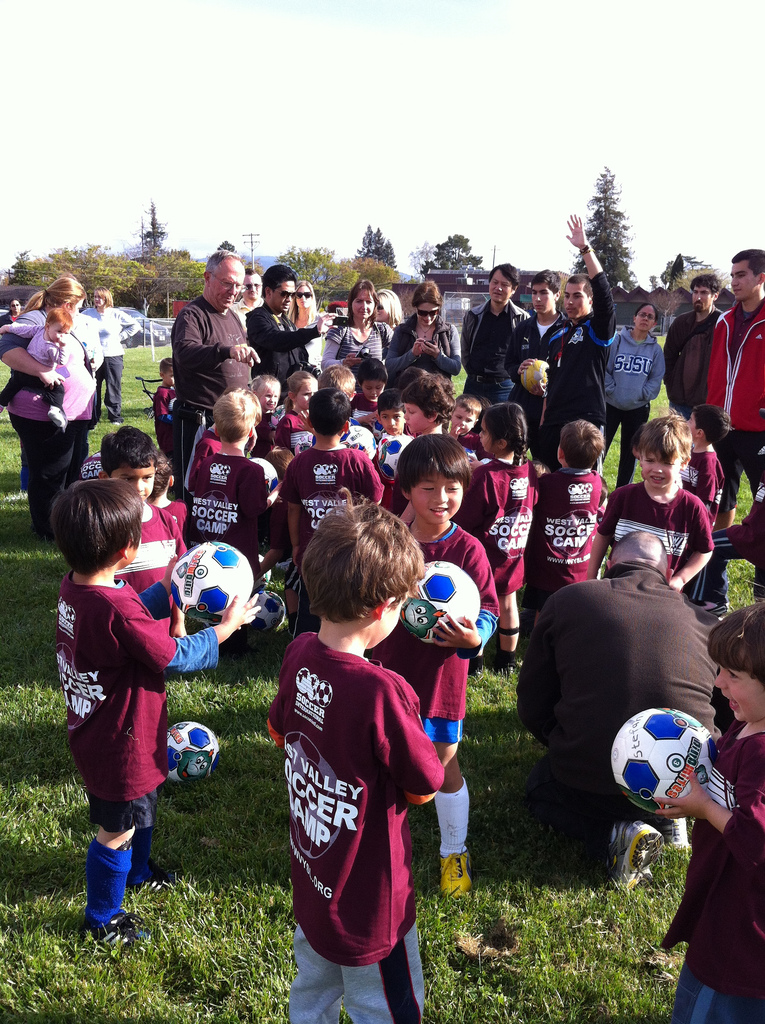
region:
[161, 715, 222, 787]
Soccer ball on the ground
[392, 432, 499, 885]
The boy holding the ball facing the camera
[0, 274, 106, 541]
Mother holding a baby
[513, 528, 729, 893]
Man kneeling in the brown shirt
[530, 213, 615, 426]
Man raising his hand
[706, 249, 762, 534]
Person in the red zip up jacket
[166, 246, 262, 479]
Older man in the brown long sleeve shirt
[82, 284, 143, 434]
Woman in the white shirt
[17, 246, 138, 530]
lady holding a toddler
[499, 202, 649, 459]
guy with hand raised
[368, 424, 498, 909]
boy wearing yellow soccer shoe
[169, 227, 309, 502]
man pointing his finger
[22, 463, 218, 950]
boy has blue socks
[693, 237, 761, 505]
guy wearing red jacket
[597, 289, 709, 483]
lady wearing gray sweatshirt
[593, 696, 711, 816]
white and blue soccer ball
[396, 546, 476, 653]
white and blue soccer ball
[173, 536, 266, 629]
white and blue soccer ball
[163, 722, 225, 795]
white and blue soccer ball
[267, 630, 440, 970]
burgundy and white shirt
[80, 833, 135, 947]
blue sock on leg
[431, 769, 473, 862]
white sock on leg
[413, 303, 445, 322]
sunglasses on woman's face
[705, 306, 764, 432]
red jacket on man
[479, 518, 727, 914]
a man in brown shirt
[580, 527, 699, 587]
the back of a man's head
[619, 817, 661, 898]
the bottom of a shoe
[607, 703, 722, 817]
a hand holding a ball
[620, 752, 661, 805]
a blue spot on the ball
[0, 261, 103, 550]
a lady holding a child on her hip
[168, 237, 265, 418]
a old man in a brown shirt standing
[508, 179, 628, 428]
a man with his hand raised wearing a watch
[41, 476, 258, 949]
a child with a long maroon colored shirt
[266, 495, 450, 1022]
a child with a long maroon colored shirt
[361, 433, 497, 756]
a child with a long maroon colored shirt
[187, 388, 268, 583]
a child with a long maroon colored shirt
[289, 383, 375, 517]
a child with a long maroon colored shirt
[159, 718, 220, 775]
a red orange and blue soccer ball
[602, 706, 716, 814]
a red orange and blue soccer ball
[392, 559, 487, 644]
a red orange and blue soccer ball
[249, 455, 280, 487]
a red orange and blue soccer ball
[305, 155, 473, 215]
Large body of skies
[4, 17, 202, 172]
Large body of skies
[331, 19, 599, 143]
Large body of skies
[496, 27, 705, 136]
Large body of skies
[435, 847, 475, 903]
Shoe on a boy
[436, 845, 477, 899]
Yellow shoe on a boy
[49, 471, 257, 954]
boy is holding the ball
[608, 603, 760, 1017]
boy is holding the ball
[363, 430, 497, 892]
boy is holding the ball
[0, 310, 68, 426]
baby is being held by the lady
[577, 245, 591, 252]
watch is on the mans wrist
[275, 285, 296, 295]
sunglasses are on ladies face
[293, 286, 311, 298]
sunglasses are on ladies face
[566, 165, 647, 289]
tree is behind the people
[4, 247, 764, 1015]
Exterior view, daytime, season, other than winter.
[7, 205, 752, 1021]
Field, showing distant trees, youthful soccer players and adults.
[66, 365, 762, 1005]
Many boys, in soccer uniforms.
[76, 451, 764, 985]
4 soccer players, holding blue and white soccer balls.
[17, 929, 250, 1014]
Short grass, appropriate for sports activity.